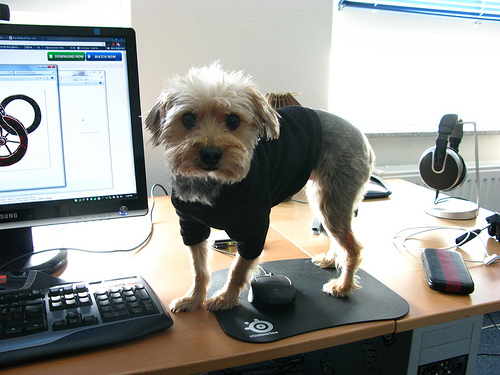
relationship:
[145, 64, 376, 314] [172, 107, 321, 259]
dog wearing shirt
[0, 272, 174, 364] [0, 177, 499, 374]
keyboard on desk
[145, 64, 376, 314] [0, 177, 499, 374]
dog standing on desk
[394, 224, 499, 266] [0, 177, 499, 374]
cord sitting on desk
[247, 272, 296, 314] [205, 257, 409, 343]
computer mouse sitting on mouse pad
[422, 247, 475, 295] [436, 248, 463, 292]
phone case with stripe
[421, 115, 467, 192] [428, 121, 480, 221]
headphones on stand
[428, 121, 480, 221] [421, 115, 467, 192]
stand for headphones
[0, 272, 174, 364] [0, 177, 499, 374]
keyboard sitting on desk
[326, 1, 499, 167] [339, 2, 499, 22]
window with blinds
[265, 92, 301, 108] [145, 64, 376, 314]
lampshade behind dog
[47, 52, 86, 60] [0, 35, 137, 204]
button on computer screen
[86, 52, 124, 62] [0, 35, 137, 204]
button for computer screen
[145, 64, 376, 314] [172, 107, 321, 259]
dog with shirt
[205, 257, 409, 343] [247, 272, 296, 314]
mouse pad with computer mouse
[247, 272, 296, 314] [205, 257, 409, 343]
computer mouse on mouse pad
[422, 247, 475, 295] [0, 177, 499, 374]
phone case on desk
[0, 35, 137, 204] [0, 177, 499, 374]
computer screen on desk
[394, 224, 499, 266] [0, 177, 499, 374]
cord on desk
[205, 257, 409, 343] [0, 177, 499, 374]
mouse pad on desk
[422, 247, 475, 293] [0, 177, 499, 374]
cellphone sitting on desk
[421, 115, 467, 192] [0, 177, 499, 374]
headphones on desk